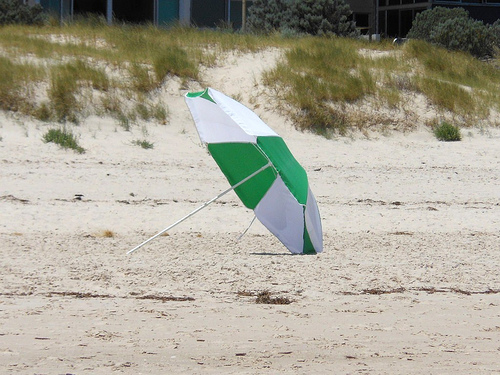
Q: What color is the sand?
A: White.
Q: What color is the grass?
A: Green.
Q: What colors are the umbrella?
A: Green and white.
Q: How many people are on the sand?
A: None.